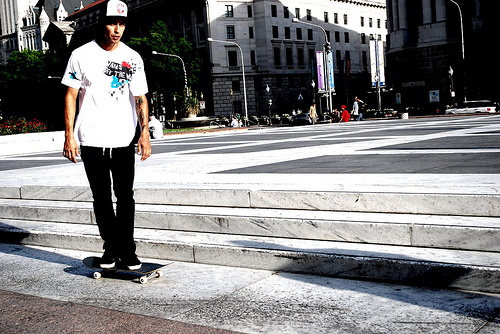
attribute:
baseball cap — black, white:
[98, 0, 135, 25]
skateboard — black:
[84, 254, 174, 282]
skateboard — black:
[80, 254, 170, 284]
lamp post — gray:
[46, 74, 63, 81]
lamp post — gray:
[149, 49, 189, 90]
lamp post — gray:
[206, 37, 248, 120]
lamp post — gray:
[291, 16, 334, 111]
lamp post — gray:
[445, 0, 467, 59]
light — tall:
[203, 32, 260, 127]